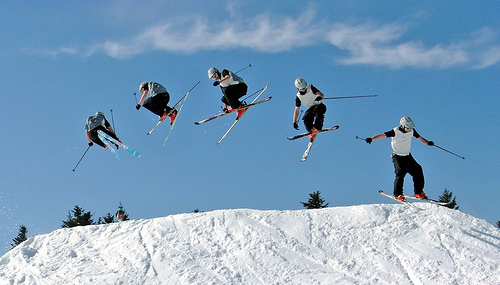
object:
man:
[81, 110, 125, 151]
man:
[132, 80, 179, 126]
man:
[206, 66, 250, 119]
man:
[292, 77, 329, 143]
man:
[363, 114, 438, 201]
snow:
[2, 197, 499, 285]